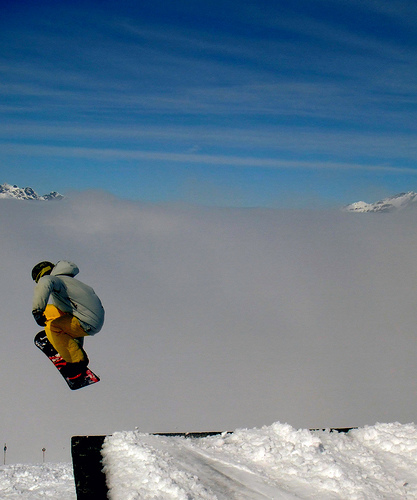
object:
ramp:
[0, 268, 416, 423]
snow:
[103, 423, 416, 497]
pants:
[41, 304, 91, 368]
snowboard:
[31, 326, 103, 391]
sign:
[2, 440, 10, 465]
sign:
[39, 441, 49, 465]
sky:
[0, 1, 413, 204]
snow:
[1, 459, 75, 500]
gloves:
[32, 304, 47, 330]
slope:
[67, 427, 415, 455]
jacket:
[28, 259, 108, 339]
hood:
[50, 258, 79, 277]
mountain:
[0, 180, 65, 207]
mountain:
[342, 184, 416, 212]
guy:
[30, 256, 107, 379]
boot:
[55, 352, 90, 386]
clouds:
[256, 69, 413, 190]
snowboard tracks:
[149, 425, 348, 499]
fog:
[1, 193, 416, 432]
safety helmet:
[28, 259, 55, 282]